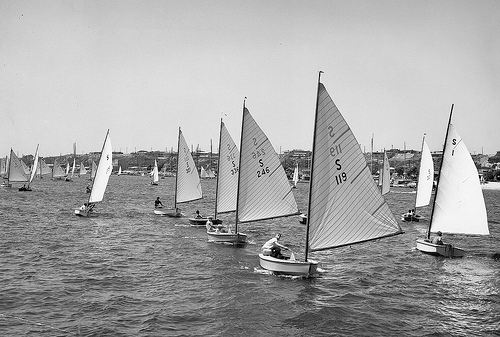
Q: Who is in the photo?
A: Sailors.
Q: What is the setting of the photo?
A: A boat race.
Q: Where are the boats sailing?
A: In the water.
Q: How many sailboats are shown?
A: At least fifteen.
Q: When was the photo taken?
A: Daytime.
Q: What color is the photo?
A: Black and white.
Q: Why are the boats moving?
A: It is windy.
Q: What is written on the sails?
A: Letters and numbers.